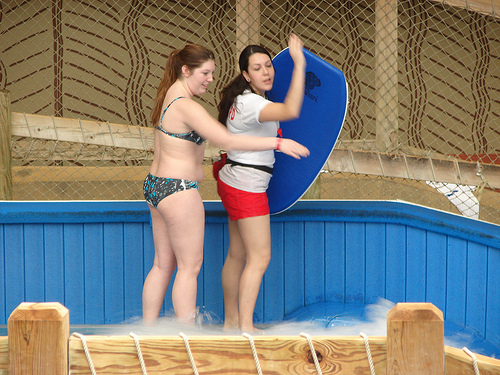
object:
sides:
[1, 198, 499, 366]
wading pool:
[0, 197, 499, 375]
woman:
[141, 44, 310, 327]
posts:
[385, 303, 450, 374]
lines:
[119, 1, 152, 127]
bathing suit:
[142, 96, 206, 208]